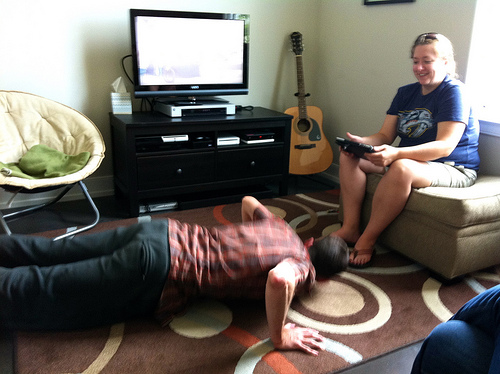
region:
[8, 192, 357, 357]
man doing push-ups on a carpet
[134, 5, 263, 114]
TV standing on a DVD player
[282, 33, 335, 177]
an acoustic guitar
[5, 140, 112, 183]
a green throw on a chair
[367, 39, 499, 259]
woman sitting on an ottoman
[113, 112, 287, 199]
a black entertainment unit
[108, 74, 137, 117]
a box of tissue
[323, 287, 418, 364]
a colorful carpet with abstract patterns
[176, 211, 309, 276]
man wearing a plaid shirt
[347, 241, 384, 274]
woman wearing flip flops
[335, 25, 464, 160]
woman in blue and white shirt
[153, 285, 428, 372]
rug with circles on it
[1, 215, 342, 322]
person doing a push up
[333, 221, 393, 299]
sandal with a brown strap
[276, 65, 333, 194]
brown acoustic guitar on stand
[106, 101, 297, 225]
black stand for t.v.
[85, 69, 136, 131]
tissues in a box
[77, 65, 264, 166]
t.v. on a stand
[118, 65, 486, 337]
two people in a living room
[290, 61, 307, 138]
strings on a guitar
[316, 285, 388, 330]
brown disc on the floor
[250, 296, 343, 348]
man's hand balancing on the floor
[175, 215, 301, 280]
pink and black shirt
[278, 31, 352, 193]
guitar on the wall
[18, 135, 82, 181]
green fabric in the chair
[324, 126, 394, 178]
woman holding black tablet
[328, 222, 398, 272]
brown flip flops on woman's feet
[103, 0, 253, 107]
black edge of television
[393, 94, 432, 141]
white symbol on blue shirt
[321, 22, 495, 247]
woman sitting on sofa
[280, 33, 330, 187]
an acoustic guitar in corner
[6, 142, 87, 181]
a green pillow in chair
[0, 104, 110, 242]
a white chair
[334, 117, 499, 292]
a tan foot stool woman is sitting on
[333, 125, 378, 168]
a woman is playing with her tablet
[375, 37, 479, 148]
a woman wearing a blue shirt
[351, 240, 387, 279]
a woman wearing a thong on left foot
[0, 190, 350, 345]
a guy is on the rug doing push ups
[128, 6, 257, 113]
a tv on counter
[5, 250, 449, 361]
a brown plush spiral rug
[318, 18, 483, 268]
a woman on an ottoman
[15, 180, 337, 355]
a man doing push ups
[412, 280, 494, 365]
a person in blue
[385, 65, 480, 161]
a navy shirt on a woman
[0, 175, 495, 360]
a brown patterned rug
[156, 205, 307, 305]
a red plaid shirt on a man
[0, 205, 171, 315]
gray pants on a man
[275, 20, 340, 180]
a guitar in a corner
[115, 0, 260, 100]
a flat screen television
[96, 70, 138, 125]
a white tissue box